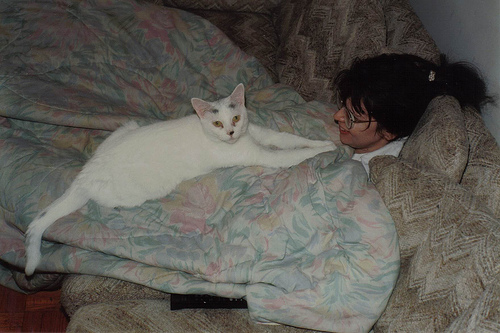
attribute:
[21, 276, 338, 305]
cat — white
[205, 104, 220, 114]
spot — black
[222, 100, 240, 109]
spot — black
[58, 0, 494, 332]
couch — chevron-patterned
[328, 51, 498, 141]
hair — dark brown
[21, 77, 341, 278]
cat — white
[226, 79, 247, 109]
ear — pink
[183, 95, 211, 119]
ear — pink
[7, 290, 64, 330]
floors — wood, parquet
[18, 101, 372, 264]
cat — white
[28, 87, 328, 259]
cat — white